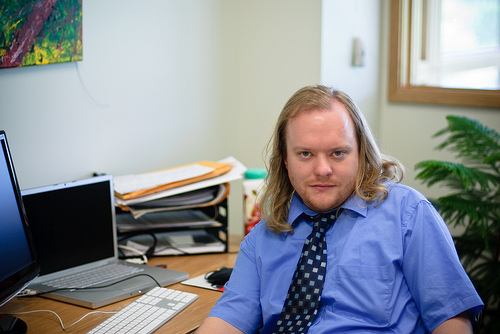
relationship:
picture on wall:
[15, 27, 67, 71] [119, 34, 180, 81]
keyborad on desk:
[94, 303, 208, 331] [186, 312, 203, 331]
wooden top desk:
[33, 307, 44, 323] [186, 312, 203, 331]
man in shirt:
[263, 120, 365, 216] [354, 232, 381, 285]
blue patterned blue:
[319, 242, 348, 296] [275, 211, 348, 330]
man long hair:
[263, 120, 365, 216] [257, 178, 312, 254]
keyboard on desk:
[94, 303, 208, 331] [186, 312, 203, 331]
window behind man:
[377, 9, 442, 114] [263, 120, 365, 216]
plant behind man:
[451, 103, 497, 224] [263, 120, 365, 216]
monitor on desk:
[36, 164, 118, 260] [186, 312, 203, 331]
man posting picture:
[263, 120, 365, 216] [15, 27, 67, 71]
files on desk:
[156, 176, 193, 200] [186, 312, 203, 331]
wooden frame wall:
[33, 307, 44, 323] [119, 34, 180, 81]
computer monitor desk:
[11, 181, 45, 298] [186, 312, 203, 331]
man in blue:
[263, 120, 365, 216] [319, 242, 348, 296]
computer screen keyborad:
[11, 181, 45, 298] [84, 287, 200, 334]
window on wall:
[377, 9, 442, 114] [119, 34, 180, 81]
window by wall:
[377, 9, 442, 114] [119, 34, 180, 81]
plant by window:
[451, 103, 497, 224] [377, 9, 442, 114]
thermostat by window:
[345, 34, 380, 66] [377, 9, 442, 114]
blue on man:
[275, 211, 348, 330] [263, 120, 365, 216]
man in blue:
[263, 120, 365, 216] [275, 211, 348, 330]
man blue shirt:
[263, 120, 365, 216] [354, 232, 381, 285]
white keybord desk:
[97, 310, 179, 319] [186, 312, 203, 331]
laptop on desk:
[40, 167, 122, 306] [186, 312, 203, 331]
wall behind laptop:
[119, 34, 180, 81] [40, 167, 122, 306]